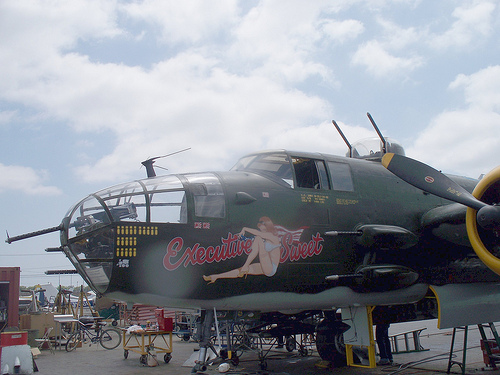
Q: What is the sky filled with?
A: White cloud.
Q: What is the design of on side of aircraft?
A: A woman.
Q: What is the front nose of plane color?
A: Black.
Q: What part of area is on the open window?
A: Cockpit.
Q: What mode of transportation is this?
A: Airplane.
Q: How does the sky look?
A: Partly cloudy.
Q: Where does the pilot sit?
A: In the cockpit.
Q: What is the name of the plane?
A: Executive Sweet.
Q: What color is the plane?
A: Black and yellow.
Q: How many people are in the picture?
A: One.